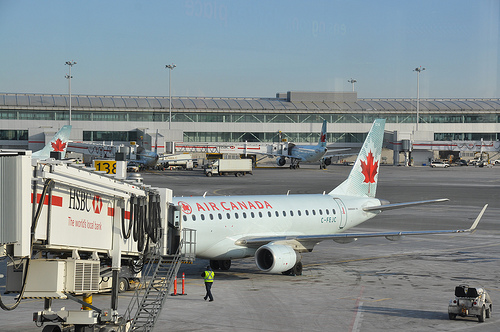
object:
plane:
[169, 118, 487, 275]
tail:
[327, 118, 388, 200]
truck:
[204, 158, 253, 176]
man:
[200, 265, 215, 303]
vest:
[201, 266, 219, 283]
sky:
[0, 0, 500, 99]